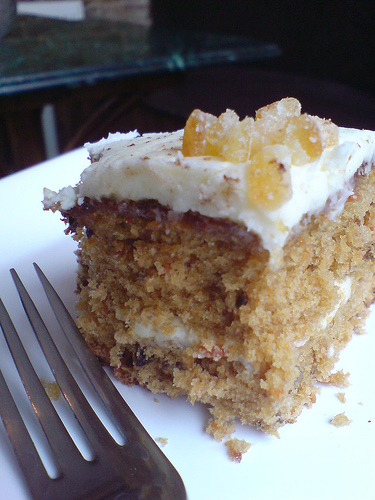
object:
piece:
[41, 184, 86, 225]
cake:
[321, 135, 374, 360]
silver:
[104, 465, 151, 488]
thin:
[177, 330, 191, 346]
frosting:
[309, 169, 334, 192]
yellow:
[181, 113, 219, 157]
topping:
[270, 86, 299, 130]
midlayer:
[339, 277, 358, 297]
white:
[161, 172, 195, 197]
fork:
[2, 323, 23, 415]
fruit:
[177, 111, 207, 151]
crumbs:
[222, 436, 248, 458]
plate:
[266, 449, 354, 496]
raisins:
[120, 346, 142, 367]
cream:
[347, 129, 374, 154]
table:
[47, 23, 132, 52]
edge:
[33, 242, 54, 295]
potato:
[237, 131, 262, 152]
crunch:
[296, 121, 324, 156]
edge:
[27, 261, 46, 277]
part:
[234, 36, 259, 60]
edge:
[92, 130, 141, 153]